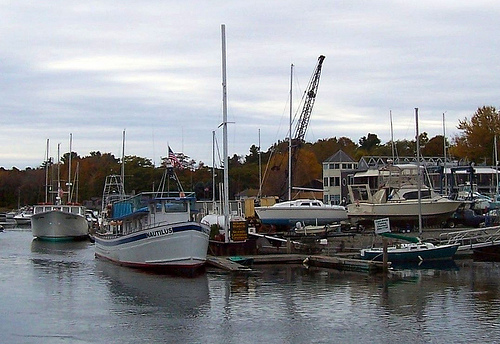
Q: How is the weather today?
A: It is cloudy.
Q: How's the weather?
A: It is cloudy.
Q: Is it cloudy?
A: Yes, it is cloudy.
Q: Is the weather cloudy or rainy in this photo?
A: It is cloudy.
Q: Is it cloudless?
A: No, it is cloudy.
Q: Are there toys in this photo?
A: No, there are no toys.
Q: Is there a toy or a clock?
A: No, there are no toys or clocks.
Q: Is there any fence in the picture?
A: No, there are no fences.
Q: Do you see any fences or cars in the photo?
A: No, there are no fences or cars.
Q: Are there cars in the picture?
A: No, there are no cars.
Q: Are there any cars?
A: No, there are no cars.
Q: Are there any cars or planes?
A: No, there are no cars or planes.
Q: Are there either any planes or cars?
A: No, there are no cars or planes.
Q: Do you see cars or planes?
A: No, there are no cars or planes.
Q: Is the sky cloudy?
A: Yes, the sky is cloudy.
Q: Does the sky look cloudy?
A: Yes, the sky is cloudy.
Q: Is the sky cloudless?
A: No, the sky is cloudy.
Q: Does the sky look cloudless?
A: No, the sky is cloudy.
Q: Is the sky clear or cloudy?
A: The sky is cloudy.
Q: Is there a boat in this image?
A: Yes, there is a boat.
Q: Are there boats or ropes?
A: Yes, there is a boat.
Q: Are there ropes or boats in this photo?
A: Yes, there is a boat.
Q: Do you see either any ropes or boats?
A: Yes, there is a boat.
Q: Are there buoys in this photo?
A: No, there are no buoys.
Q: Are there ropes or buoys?
A: No, there are no buoys or ropes.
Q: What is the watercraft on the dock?
A: The watercraft is a boat.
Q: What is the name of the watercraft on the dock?
A: The watercraft is a boat.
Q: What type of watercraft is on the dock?
A: The watercraft is a boat.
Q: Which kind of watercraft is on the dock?
A: The watercraft is a boat.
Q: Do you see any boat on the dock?
A: Yes, there is a boat on the dock.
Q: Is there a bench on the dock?
A: No, there is a boat on the dock.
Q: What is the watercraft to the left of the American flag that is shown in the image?
A: The watercraft is a boat.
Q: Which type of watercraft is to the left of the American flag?
A: The watercraft is a boat.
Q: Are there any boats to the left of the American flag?
A: Yes, there is a boat to the left of the American flag.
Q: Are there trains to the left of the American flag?
A: No, there is a boat to the left of the American flag.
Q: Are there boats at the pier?
A: Yes, there is a boat at the pier.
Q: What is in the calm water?
A: The boat is in the water.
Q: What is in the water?
A: The boat is in the water.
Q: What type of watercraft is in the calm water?
A: The watercraft is a boat.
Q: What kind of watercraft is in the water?
A: The watercraft is a boat.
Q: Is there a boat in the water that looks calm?
A: Yes, there is a boat in the water.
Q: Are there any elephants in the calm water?
A: No, there is a boat in the water.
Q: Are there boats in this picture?
A: Yes, there is a boat.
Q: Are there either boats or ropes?
A: Yes, there is a boat.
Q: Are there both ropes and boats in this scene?
A: No, there is a boat but no ropes.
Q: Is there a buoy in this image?
A: No, there are no buoys.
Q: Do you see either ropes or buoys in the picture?
A: No, there are no buoys or ropes.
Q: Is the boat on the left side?
A: Yes, the boat is on the left of the image.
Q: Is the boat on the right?
A: No, the boat is on the left of the image.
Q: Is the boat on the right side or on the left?
A: The boat is on the left of the image.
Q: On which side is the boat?
A: The boat is on the left of the image.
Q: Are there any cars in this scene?
A: No, there are no cars.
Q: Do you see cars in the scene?
A: No, there are no cars.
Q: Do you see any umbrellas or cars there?
A: No, there are no cars or umbrellas.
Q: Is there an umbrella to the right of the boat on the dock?
A: No, there is an American flag to the right of the boat.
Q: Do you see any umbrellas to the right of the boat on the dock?
A: No, there is an American flag to the right of the boat.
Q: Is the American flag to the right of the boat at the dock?
A: Yes, the American flag is to the right of the boat.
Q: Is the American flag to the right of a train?
A: No, the American flag is to the right of the boat.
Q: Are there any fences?
A: No, there are no fences.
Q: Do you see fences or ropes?
A: No, there are no fences or ropes.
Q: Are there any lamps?
A: No, there are no lamps.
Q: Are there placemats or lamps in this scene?
A: No, there are no lamps or placemats.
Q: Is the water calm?
A: Yes, the water is calm.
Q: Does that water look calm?
A: Yes, the water is calm.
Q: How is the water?
A: The water is calm.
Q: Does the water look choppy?
A: No, the water is calm.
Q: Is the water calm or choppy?
A: The water is calm.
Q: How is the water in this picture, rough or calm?
A: The water is calm.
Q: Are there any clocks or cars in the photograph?
A: No, there are no cars or clocks.